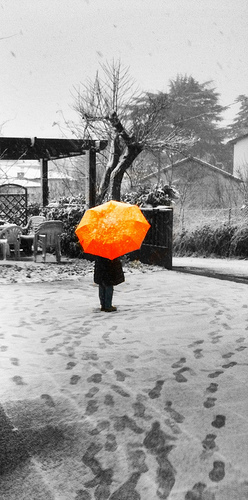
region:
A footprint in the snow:
[208, 459, 224, 482]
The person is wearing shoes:
[100, 305, 117, 312]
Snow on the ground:
[0, 255, 246, 497]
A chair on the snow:
[32, 221, 62, 261]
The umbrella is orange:
[76, 200, 149, 257]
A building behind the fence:
[137, 155, 242, 219]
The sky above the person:
[1, 0, 247, 135]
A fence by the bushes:
[175, 209, 247, 226]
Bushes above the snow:
[173, 223, 245, 256]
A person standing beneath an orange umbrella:
[75, 199, 149, 311]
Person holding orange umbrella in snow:
[74, 199, 150, 312]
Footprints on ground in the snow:
[2, 278, 246, 497]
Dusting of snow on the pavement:
[2, 402, 246, 498]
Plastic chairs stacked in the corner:
[1, 215, 63, 262]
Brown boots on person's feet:
[100, 305, 116, 311]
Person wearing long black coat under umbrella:
[74, 199, 150, 285]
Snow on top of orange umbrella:
[92, 205, 130, 241]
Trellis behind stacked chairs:
[1, 183, 27, 225]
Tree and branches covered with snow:
[51, 55, 200, 202]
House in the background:
[128, 154, 247, 208]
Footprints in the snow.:
[85, 371, 130, 414]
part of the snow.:
[29, 350, 39, 374]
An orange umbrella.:
[75, 199, 149, 259]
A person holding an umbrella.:
[73, 199, 150, 312]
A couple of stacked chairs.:
[33, 219, 63, 264]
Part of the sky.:
[26, 95, 49, 112]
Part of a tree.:
[173, 98, 189, 117]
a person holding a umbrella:
[74, 188, 157, 282]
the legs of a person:
[85, 273, 144, 318]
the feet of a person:
[91, 300, 127, 334]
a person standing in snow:
[76, 209, 165, 320]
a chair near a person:
[29, 203, 99, 324]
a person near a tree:
[58, 90, 190, 277]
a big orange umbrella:
[58, 185, 161, 291]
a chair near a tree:
[17, 134, 155, 263]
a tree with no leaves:
[119, 101, 205, 153]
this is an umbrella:
[72, 199, 148, 253]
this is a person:
[85, 242, 127, 321]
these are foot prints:
[139, 412, 176, 493]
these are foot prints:
[201, 429, 226, 481]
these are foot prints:
[203, 378, 221, 412]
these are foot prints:
[86, 370, 104, 418]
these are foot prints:
[105, 359, 129, 402]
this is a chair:
[27, 217, 72, 264]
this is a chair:
[17, 208, 48, 254]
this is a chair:
[3, 225, 26, 263]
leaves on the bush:
[161, 103, 190, 121]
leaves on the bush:
[205, 225, 230, 252]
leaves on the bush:
[231, 238, 246, 253]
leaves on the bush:
[225, 239, 237, 257]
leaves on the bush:
[201, 218, 227, 248]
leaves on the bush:
[221, 226, 244, 242]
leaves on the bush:
[67, 227, 74, 246]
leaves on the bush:
[212, 226, 231, 247]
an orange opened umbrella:
[57, 194, 167, 262]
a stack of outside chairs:
[30, 213, 66, 258]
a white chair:
[13, 200, 42, 244]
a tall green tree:
[2, 219, 24, 254]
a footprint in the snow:
[147, 378, 165, 398]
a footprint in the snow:
[206, 411, 226, 427]